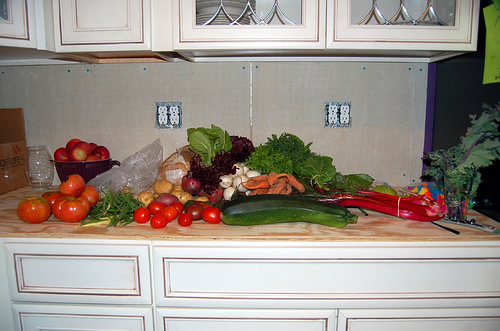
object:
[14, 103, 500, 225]
vegetable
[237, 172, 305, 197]
carrots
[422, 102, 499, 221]
refrigerator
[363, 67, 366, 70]
nail hole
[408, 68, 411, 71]
nail hole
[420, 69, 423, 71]
nail hole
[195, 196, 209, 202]
potatoes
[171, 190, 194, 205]
potatoes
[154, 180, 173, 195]
potatoes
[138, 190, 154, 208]
potatoes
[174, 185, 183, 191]
potatoes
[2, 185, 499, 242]
counter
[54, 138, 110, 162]
apples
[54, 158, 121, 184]
purple jar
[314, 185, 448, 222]
radishes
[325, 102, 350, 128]
outlet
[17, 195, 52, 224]
tomato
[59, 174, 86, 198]
tomato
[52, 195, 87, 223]
tomato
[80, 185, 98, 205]
tomato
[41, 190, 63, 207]
tomato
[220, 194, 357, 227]
cucumber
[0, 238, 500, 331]
counter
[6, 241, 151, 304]
drawer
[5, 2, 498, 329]
wall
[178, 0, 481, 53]
cabinet doors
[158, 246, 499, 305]
drawers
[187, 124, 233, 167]
spinach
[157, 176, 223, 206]
onions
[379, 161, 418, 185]
paper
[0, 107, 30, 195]
cardboard box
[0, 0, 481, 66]
cabinets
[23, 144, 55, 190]
glass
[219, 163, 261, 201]
garlic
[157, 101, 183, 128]
outlet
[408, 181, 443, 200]
balloons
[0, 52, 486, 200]
counter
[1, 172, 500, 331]
table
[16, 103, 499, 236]
food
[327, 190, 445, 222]
bunch